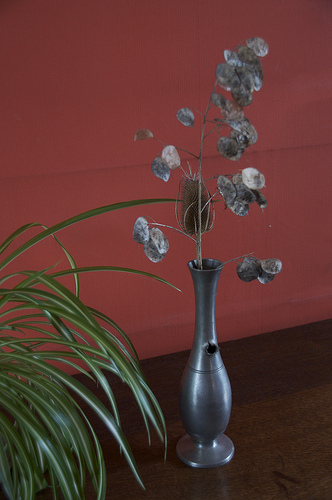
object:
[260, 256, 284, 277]
leaf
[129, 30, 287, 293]
plant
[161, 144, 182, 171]
leaf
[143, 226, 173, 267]
leaf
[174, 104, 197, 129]
leaf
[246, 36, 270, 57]
leaf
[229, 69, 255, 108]
leaf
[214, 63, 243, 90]
leaf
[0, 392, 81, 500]
leaves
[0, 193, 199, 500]
plant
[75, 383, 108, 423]
stripe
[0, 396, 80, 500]
leaf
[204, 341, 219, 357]
hole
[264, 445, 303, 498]
marks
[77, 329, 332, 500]
table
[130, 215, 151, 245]
leaf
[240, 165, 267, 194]
leaf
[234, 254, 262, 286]
leaf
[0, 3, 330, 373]
wall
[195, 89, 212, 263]
stem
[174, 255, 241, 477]
vase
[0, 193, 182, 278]
leaf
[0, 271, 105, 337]
leaf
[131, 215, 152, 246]
flower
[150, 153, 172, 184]
flower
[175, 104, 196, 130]
flower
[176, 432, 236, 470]
base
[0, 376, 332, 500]
dark brown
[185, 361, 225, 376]
line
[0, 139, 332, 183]
line